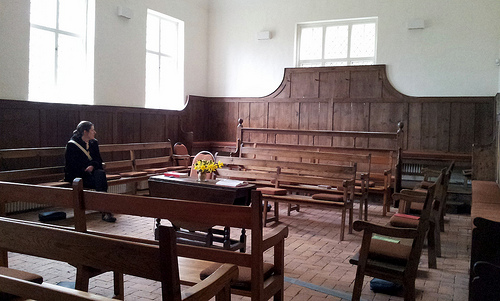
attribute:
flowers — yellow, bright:
[193, 153, 226, 175]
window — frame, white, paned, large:
[30, 4, 105, 104]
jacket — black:
[62, 143, 101, 172]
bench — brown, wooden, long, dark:
[6, 135, 182, 185]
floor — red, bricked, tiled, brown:
[290, 207, 364, 288]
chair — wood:
[352, 180, 427, 300]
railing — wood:
[222, 119, 412, 141]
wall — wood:
[204, 94, 499, 144]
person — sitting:
[70, 116, 109, 161]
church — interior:
[21, 82, 464, 299]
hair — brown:
[66, 119, 88, 143]